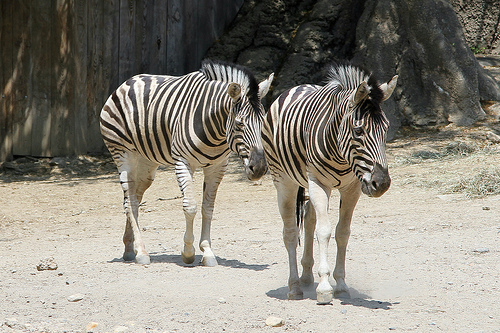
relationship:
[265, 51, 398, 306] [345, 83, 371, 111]
zebra has ear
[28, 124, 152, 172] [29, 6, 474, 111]
shadow cast by tree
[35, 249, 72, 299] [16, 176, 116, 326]
rocks on ground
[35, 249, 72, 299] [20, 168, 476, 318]
rocks on ground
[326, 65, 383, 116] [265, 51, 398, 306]
mane on zebra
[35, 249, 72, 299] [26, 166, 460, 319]
rocks on dirt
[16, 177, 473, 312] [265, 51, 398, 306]
ground under zebra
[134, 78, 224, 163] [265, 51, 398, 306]
stripes on zebra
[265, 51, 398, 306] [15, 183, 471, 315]
zebra on dirt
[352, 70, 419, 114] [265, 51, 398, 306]
ear of zebra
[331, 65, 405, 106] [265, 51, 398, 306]
mane of zebra